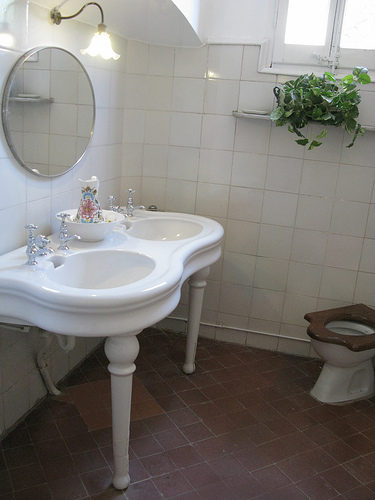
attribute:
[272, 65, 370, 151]
plant — green, small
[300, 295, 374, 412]
toilet — brown, white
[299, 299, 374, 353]
seat — wooden, brown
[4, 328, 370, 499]
floor — brown, tiled, brick, dark brown, patterned, red, light colored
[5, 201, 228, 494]
sink — white, double, porcelain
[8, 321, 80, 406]
plumbing — exposed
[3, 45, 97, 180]
mirror — round, silver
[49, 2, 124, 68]
light — gold, glass, mounted fixture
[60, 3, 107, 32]
neck — chrome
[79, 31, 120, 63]
shade — glass, fluted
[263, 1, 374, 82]
window — small, glass, double, day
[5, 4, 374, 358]
walls — square tiled, white, tiled, ceramic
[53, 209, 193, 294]
basins — flowered, double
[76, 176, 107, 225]
pitcher — floral, flowered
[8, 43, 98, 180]
frame — silver, metal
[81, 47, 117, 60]
edge — scallop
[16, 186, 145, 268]
faucets — silver, shiny, double, chrome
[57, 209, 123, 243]
basin — white